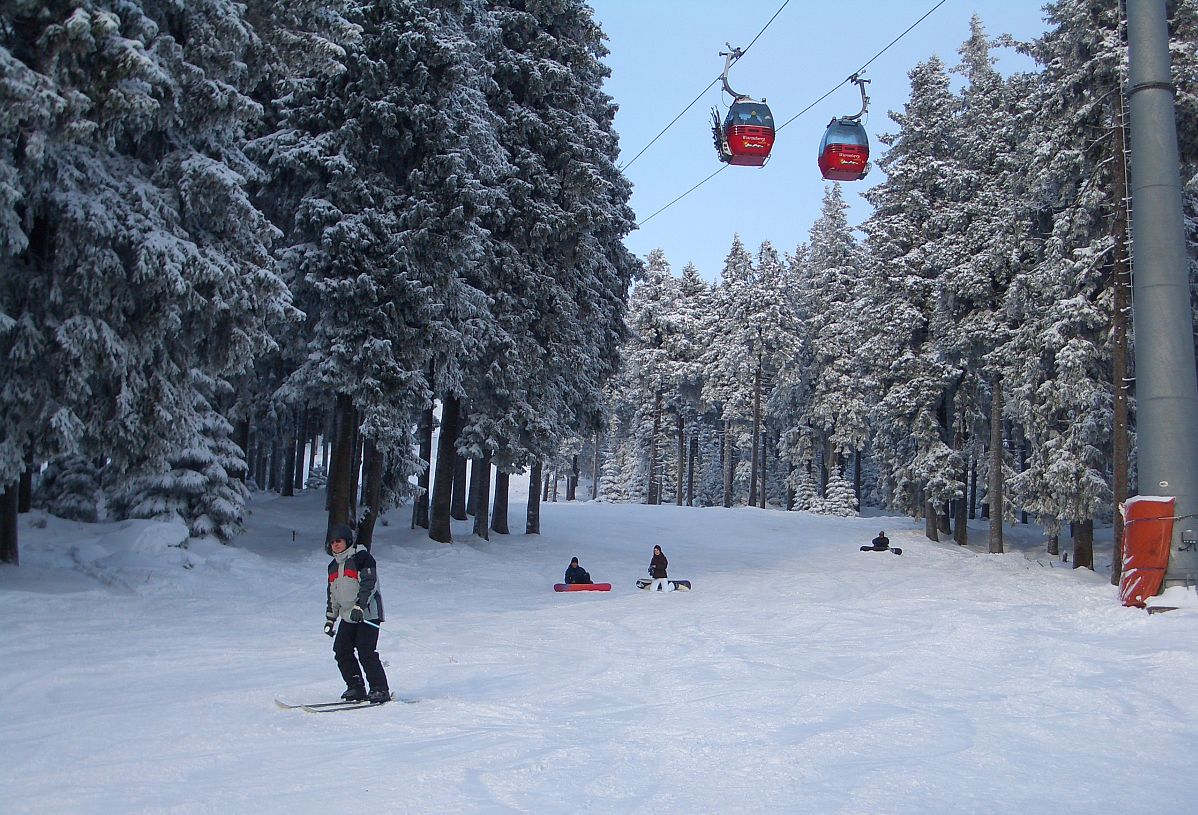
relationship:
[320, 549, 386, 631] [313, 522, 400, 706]
jacket of man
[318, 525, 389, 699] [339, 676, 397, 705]
man wearing shoes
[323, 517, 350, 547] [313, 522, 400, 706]
hat of a man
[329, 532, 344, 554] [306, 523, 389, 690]
face of a man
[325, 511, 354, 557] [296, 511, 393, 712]
head of man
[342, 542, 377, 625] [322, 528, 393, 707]
left arm of man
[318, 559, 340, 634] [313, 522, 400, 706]
right arm of man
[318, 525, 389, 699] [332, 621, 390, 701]
man wearing pants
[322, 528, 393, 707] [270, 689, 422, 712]
man on skis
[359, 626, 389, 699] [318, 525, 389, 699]
left leg of man